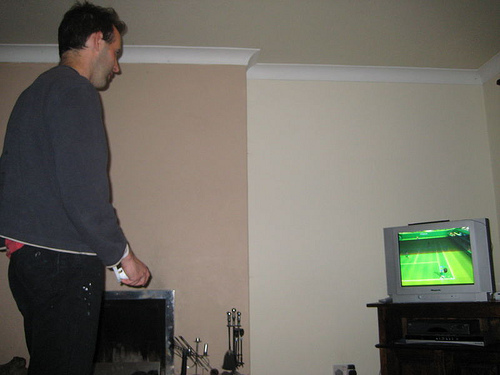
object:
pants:
[3, 248, 106, 375]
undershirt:
[5, 237, 97, 256]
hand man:
[0, 1, 152, 375]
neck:
[57, 59, 100, 83]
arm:
[57, 72, 131, 266]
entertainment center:
[366, 299, 500, 375]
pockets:
[18, 246, 63, 297]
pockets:
[71, 253, 108, 311]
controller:
[110, 256, 127, 285]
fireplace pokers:
[225, 311, 231, 356]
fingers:
[119, 273, 138, 285]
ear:
[93, 31, 103, 52]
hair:
[57, 0, 131, 58]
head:
[56, 2, 129, 92]